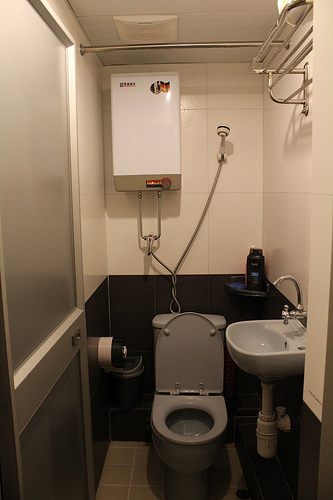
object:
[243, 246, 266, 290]
shampoo bottle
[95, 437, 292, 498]
floor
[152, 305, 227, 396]
seat lid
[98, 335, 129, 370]
dispenser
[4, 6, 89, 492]
door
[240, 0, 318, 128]
shelving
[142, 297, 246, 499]
toilet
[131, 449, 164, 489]
tiles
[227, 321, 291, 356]
bowl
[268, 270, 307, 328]
faucet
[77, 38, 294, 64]
rod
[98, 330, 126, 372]
towel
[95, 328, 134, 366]
holder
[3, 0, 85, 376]
glass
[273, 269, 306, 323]
head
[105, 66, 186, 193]
box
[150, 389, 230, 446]
seat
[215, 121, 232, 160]
shower head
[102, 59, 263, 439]
wall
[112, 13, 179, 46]
fan vent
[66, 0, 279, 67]
ceiling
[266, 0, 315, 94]
rods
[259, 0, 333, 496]
walls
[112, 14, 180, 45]
vent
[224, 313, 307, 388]
sink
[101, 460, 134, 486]
tile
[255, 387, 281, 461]
drainage pipe